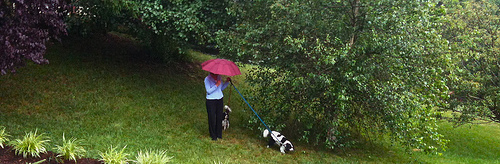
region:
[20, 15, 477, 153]
woman walking dogs in park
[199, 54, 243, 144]
woman under open red umbrella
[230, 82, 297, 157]
black and white dog on blue leash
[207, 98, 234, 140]
front of dog behind woman's leg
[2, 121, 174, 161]
spiky plants in a row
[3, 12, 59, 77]
purple flowers in deep shade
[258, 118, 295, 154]
The dog is on a leash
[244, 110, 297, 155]
The dog is on a blue leash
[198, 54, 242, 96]
The person is holding a umbrella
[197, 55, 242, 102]
The person is holding a pink umbrella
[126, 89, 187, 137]
Large body of grass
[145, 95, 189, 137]
Large body of green grass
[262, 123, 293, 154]
Dog is walking on the grass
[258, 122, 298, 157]
White and dog walking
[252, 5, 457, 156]
Large tree by the dog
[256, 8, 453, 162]
Large green tree near the dog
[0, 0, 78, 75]
purple leaves from a tree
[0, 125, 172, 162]
dirt bed with flowers planted in it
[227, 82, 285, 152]
blue leash attached to dog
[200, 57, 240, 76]
pink umbrella shading woman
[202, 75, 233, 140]
woman holding an umbrella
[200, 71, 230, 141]
woman wearing a blue shirt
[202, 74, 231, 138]
woman wearing a pair of black pants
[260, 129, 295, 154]
dog on a leash being walked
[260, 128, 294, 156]
a black and white dog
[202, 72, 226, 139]
woman walking her dog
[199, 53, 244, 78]
A opened red umbrella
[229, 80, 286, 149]
A thick blue dog leash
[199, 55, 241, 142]
A women standing under an umbrella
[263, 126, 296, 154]
A small black spotted dog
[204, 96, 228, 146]
A pair of black pants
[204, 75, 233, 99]
A long sleeved blue shirt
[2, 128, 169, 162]
A landscaped piece of yard.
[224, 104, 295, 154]
Two dogs outside on leashes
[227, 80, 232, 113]
A thin red leash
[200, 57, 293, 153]
person walking two dogs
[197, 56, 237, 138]
person holding an umbrella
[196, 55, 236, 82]
the umbrella is red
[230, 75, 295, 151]
dog's leash is blue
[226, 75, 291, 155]
dog is on a leash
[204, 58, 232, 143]
person wearing blue shirt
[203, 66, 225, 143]
person wearing black pants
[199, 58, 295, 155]
dog is in front of person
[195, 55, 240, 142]
person standing on grass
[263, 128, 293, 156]
black and white dog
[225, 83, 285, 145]
blue leash on dog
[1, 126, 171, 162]
green decorative plants in the foreground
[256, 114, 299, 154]
dog standing next to bush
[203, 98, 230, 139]
woman wearing black pants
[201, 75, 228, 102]
woman wearing a blue shirt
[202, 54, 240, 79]
woman holding a red umbrella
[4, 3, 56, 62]
purple leaves on the tree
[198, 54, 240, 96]
woman holding a red umbrella